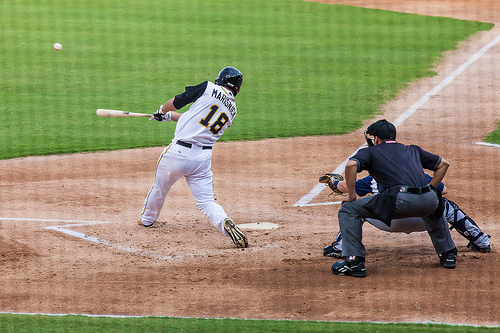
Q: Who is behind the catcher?
A: Umpire.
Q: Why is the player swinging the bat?
A: To hit the ball.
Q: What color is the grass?
A: Green.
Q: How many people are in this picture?
A: Three.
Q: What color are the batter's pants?
A: White.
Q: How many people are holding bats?
A: One.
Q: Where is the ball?
A: In the air.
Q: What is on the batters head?
A: A helmet.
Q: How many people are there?
A: Three.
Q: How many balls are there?
A: One.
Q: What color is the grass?
A: Green.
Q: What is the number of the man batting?
A: 18.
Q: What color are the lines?
A: White.